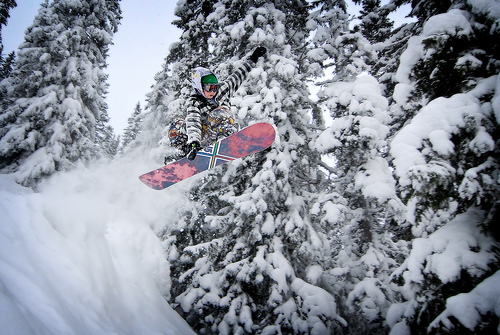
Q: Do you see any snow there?
A: Yes, there is snow.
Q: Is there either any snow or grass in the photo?
A: Yes, there is snow.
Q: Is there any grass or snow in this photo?
A: Yes, there is snow.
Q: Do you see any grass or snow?
A: Yes, there is snow.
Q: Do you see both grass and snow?
A: No, there is snow but no grass.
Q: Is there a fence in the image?
A: No, there are no fences.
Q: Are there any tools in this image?
A: No, there are no tools.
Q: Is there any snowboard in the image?
A: Yes, there is a snowboard.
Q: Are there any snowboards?
A: Yes, there is a snowboard.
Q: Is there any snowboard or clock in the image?
A: Yes, there is a snowboard.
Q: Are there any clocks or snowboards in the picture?
A: Yes, there is a snowboard.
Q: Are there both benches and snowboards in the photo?
A: No, there is a snowboard but no benches.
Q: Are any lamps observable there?
A: No, there are no lamps.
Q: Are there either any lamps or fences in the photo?
A: No, there are no lamps or fences.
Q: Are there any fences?
A: No, there are no fences.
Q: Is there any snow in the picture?
A: Yes, there is snow.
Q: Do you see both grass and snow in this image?
A: No, there is snow but no grass.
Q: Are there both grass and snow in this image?
A: No, there is snow but no grass.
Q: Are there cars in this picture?
A: No, there are no cars.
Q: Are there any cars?
A: No, there are no cars.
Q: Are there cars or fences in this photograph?
A: No, there are no cars or fences.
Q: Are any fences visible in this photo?
A: No, there are no fences.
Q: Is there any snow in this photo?
A: Yes, there is snow.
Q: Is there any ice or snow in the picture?
A: Yes, there is snow.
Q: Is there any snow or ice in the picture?
A: Yes, there is snow.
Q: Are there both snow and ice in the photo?
A: No, there is snow but no ice.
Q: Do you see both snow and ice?
A: No, there is snow but no ice.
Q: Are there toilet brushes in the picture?
A: No, there are no toilet brushes.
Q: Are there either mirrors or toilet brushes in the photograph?
A: No, there are no toilet brushes or mirrors.